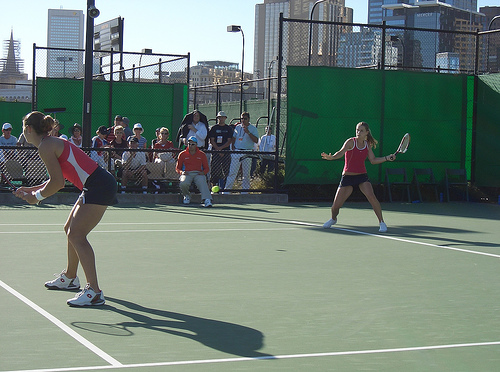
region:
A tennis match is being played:
[2, 97, 499, 368]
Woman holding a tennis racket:
[316, 117, 414, 237]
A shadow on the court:
[68, 282, 288, 363]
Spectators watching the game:
[2, 106, 281, 195]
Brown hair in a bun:
[18, 109, 58, 149]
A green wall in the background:
[280, 55, 476, 204]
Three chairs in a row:
[379, 159, 474, 207]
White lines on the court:
[2, 220, 499, 366]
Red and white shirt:
[57, 137, 98, 192]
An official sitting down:
[174, 133, 215, 213]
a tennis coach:
[175, 138, 214, 205]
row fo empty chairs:
[379, 165, 471, 202]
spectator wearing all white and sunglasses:
[226, 111, 257, 188]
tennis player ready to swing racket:
[321, 118, 414, 239]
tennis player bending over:
[7, 111, 118, 303]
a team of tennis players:
[4, 110, 411, 304]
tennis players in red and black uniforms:
[7, 109, 411, 311]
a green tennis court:
[1, 193, 497, 366]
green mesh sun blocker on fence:
[0, 63, 478, 178]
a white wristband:
[29, 186, 44, 202]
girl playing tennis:
[318, 121, 396, 233]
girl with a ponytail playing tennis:
[320, 121, 387, 233]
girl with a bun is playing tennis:
[10, 110, 120, 307]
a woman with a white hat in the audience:
[128, 122, 148, 149]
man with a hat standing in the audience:
[208, 110, 233, 186]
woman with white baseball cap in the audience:
[1, 122, 17, 145]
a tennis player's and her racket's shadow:
[70, 295, 276, 360]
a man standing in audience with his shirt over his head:
[177, 109, 211, 184]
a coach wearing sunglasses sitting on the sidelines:
[175, 135, 217, 208]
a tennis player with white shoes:
[320, 122, 397, 233]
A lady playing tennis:
[15, 110, 117, 305]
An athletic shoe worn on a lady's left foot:
[67, 285, 103, 304]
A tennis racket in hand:
[392, 132, 409, 157]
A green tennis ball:
[212, 184, 218, 191]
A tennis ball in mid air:
[210, 185, 217, 192]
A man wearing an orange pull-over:
[172, 135, 210, 206]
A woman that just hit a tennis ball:
[320, 120, 407, 231]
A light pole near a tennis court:
[226, 23, 244, 120]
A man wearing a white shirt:
[259, 125, 279, 182]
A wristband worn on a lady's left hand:
[33, 191, 44, 200]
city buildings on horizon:
[0, 2, 495, 65]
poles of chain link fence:
[276, 15, 482, 65]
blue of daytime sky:
[0, 2, 255, 69]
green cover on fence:
[278, 19, 474, 194]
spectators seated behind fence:
[0, 115, 167, 180]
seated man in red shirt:
[176, 136, 211, 206]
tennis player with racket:
[318, 119, 409, 231]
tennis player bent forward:
[2, 108, 119, 305]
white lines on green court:
[0, 219, 497, 369]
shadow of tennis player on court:
[72, 294, 273, 362]